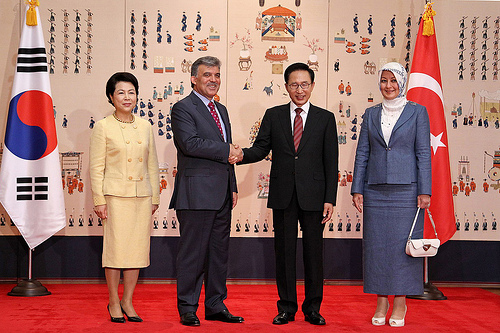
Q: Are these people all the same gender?
A: No, they are both male and female.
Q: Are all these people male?
A: No, they are both male and female.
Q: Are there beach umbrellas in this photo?
A: No, there are no beach umbrellas.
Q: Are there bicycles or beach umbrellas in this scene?
A: No, there are no beach umbrellas or bicycles.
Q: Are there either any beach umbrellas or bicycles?
A: No, there are no beach umbrellas or bicycles.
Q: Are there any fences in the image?
A: No, there are no fences.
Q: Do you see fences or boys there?
A: No, there are no fences or boys.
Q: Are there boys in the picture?
A: No, there are no boys.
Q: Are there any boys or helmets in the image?
A: No, there are no boys or helmets.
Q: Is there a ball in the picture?
A: No, there are no balls.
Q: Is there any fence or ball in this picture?
A: No, there are no balls or fences.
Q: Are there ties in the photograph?
A: Yes, there is a tie.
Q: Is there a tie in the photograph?
A: Yes, there is a tie.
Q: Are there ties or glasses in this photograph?
A: Yes, there is a tie.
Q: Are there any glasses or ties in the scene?
A: Yes, there is a tie.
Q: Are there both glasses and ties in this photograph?
A: Yes, there are both a tie and glasses.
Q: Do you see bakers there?
A: No, there are no bakers.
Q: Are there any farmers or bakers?
A: No, there are no bakers or farmers.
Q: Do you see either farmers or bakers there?
A: No, there are no bakers or farmers.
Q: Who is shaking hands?
A: The man is shaking hands.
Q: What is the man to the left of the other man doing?
A: The man is shaking hands.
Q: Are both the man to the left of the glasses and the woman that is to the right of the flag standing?
A: Yes, both the man and the woman are standing.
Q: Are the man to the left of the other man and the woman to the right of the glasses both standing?
A: Yes, both the man and the woman are standing.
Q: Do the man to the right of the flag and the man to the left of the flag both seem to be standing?
A: Yes, both the man and the man are standing.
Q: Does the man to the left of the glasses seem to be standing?
A: Yes, the man is standing.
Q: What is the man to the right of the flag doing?
A: The man is standing.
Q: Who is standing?
A: The man is standing.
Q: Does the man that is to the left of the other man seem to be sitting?
A: No, the man is standing.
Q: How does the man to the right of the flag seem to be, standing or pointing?
A: The man is standing.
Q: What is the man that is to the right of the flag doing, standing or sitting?
A: The man is standing.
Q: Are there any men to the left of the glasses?
A: Yes, there is a man to the left of the glasses.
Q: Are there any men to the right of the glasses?
A: No, the man is to the left of the glasses.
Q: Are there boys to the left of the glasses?
A: No, there is a man to the left of the glasses.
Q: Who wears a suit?
A: The man wears a suit.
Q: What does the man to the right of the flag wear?
A: The man wears a suit.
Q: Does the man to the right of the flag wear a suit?
A: Yes, the man wears a suit.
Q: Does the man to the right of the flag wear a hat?
A: No, the man wears a suit.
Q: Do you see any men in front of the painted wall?
A: Yes, there is a man in front of the wall.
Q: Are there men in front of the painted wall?
A: Yes, there is a man in front of the wall.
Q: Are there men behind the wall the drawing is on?
A: No, the man is in front of the wall.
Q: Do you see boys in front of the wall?
A: No, there is a man in front of the wall.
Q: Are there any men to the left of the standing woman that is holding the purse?
A: Yes, there is a man to the left of the woman.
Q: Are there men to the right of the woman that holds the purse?
A: No, the man is to the left of the woman.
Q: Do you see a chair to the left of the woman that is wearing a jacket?
A: No, there is a man to the left of the woman.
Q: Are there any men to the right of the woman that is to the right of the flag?
A: Yes, there is a man to the right of the woman.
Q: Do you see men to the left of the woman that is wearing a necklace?
A: No, the man is to the right of the woman.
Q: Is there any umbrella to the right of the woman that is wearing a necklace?
A: No, there is a man to the right of the woman.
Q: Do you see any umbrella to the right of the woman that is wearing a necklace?
A: No, there is a man to the right of the woman.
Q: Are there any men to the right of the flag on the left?
A: Yes, there is a man to the right of the flag.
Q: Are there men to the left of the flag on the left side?
A: No, the man is to the right of the flag.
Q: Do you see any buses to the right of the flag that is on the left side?
A: No, there is a man to the right of the flag.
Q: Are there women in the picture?
A: Yes, there is a woman.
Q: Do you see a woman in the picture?
A: Yes, there is a woman.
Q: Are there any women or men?
A: Yes, there is a woman.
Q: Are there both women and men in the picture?
A: Yes, there are both a woman and a man.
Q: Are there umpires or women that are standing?
A: Yes, the woman is standing.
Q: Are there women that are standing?
A: Yes, there is a woman that is standing.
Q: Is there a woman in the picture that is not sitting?
A: Yes, there is a woman that is standing.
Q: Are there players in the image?
A: No, there are no players.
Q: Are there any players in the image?
A: No, there are no players.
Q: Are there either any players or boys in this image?
A: No, there are no players or boys.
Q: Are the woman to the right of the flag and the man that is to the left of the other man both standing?
A: Yes, both the woman and the man are standing.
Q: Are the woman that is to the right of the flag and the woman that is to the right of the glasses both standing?
A: Yes, both the woman and the woman are standing.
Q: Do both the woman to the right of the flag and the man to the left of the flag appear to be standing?
A: Yes, both the woman and the man are standing.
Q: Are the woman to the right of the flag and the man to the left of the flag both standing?
A: Yes, both the woman and the man are standing.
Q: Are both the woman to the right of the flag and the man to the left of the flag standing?
A: Yes, both the woman and the man are standing.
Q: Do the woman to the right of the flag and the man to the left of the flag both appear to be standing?
A: Yes, both the woman and the man are standing.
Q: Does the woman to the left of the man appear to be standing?
A: Yes, the woman is standing.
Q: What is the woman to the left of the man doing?
A: The woman is standing.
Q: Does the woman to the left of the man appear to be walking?
A: No, the woman is standing.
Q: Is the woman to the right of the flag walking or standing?
A: The woman is standing.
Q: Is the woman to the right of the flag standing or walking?
A: The woman is standing.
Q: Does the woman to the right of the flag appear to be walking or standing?
A: The woman is standing.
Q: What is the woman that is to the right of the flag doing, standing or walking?
A: The woman is standing.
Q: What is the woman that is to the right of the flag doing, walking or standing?
A: The woman is standing.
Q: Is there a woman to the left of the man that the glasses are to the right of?
A: Yes, there is a woman to the left of the man.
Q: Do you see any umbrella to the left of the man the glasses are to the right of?
A: No, there is a woman to the left of the man.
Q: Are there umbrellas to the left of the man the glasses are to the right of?
A: No, there is a woman to the left of the man.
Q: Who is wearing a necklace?
A: The woman is wearing a necklace.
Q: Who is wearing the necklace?
A: The woman is wearing a necklace.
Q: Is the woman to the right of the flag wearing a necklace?
A: Yes, the woman is wearing a necklace.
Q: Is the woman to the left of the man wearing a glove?
A: No, the woman is wearing a necklace.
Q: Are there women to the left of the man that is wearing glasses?
A: Yes, there is a woman to the left of the man.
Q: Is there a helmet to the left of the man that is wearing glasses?
A: No, there is a woman to the left of the man.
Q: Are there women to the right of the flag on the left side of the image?
A: Yes, there is a woman to the right of the flag.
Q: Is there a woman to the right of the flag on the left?
A: Yes, there is a woman to the right of the flag.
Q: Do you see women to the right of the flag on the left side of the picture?
A: Yes, there is a woman to the right of the flag.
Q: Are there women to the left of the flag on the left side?
A: No, the woman is to the right of the flag.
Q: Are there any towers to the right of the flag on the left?
A: No, there is a woman to the right of the flag.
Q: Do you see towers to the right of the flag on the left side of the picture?
A: No, there is a woman to the right of the flag.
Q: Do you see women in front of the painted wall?
A: Yes, there is a woman in front of the wall.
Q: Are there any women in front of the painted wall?
A: Yes, there is a woman in front of the wall.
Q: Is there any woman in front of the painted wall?
A: Yes, there is a woman in front of the wall.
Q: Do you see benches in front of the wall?
A: No, there is a woman in front of the wall.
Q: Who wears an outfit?
A: The woman wears an outfit.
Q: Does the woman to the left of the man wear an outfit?
A: Yes, the woman wears an outfit.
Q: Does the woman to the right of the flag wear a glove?
A: No, the woman wears an outfit.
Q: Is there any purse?
A: Yes, there is a purse.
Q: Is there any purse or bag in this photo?
A: Yes, there is a purse.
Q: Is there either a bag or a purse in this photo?
A: Yes, there is a purse.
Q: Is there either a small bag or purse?
A: Yes, there is a small purse.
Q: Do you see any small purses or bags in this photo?
A: Yes, there is a small purse.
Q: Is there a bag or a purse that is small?
A: Yes, the purse is small.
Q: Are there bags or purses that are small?
A: Yes, the purse is small.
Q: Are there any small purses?
A: Yes, there is a small purse.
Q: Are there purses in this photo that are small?
A: Yes, there is a purse that is small.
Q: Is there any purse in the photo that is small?
A: Yes, there is a purse that is small.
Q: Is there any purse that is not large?
A: Yes, there is a small purse.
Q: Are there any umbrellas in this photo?
A: No, there are no umbrellas.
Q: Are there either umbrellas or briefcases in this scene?
A: No, there are no umbrellas or briefcases.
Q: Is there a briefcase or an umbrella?
A: No, there are no umbrellas or briefcases.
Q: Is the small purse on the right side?
A: Yes, the purse is on the right of the image.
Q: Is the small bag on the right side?
A: Yes, the purse is on the right of the image.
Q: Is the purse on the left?
A: No, the purse is on the right of the image.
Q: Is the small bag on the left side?
A: No, the purse is on the right of the image.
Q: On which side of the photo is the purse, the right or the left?
A: The purse is on the right of the image.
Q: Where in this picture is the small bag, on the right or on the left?
A: The purse is on the right of the image.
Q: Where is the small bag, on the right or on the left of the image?
A: The purse is on the right of the image.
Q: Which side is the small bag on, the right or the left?
A: The purse is on the right of the image.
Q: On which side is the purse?
A: The purse is on the right of the image.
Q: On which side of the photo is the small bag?
A: The purse is on the right of the image.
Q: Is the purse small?
A: Yes, the purse is small.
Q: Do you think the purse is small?
A: Yes, the purse is small.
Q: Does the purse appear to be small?
A: Yes, the purse is small.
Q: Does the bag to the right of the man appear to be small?
A: Yes, the purse is small.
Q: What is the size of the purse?
A: The purse is small.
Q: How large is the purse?
A: The purse is small.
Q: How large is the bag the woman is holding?
A: The purse is small.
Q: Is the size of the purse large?
A: No, the purse is small.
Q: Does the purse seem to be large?
A: No, the purse is small.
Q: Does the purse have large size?
A: No, the purse is small.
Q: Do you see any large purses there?
A: No, there is a purse but it is small.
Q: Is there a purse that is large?
A: No, there is a purse but it is small.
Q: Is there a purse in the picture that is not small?
A: No, there is a purse but it is small.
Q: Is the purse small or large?
A: The purse is small.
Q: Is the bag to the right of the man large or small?
A: The purse is small.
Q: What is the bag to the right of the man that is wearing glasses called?
A: The bag is a purse.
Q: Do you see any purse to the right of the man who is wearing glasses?
A: Yes, there is a purse to the right of the man.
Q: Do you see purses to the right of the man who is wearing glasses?
A: Yes, there is a purse to the right of the man.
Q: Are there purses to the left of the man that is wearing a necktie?
A: No, the purse is to the right of the man.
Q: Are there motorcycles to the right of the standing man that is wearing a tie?
A: No, there is a purse to the right of the man.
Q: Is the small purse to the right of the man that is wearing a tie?
A: Yes, the purse is to the right of the man.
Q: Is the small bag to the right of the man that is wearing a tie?
A: Yes, the purse is to the right of the man.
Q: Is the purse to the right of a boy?
A: No, the purse is to the right of the man.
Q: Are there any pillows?
A: No, there are no pillows.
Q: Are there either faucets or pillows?
A: No, there are no pillows or faucets.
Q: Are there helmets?
A: No, there are no helmets.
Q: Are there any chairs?
A: No, there are no chairs.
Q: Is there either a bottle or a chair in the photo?
A: No, there are no chairs or bottles.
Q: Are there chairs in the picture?
A: No, there are no chairs.